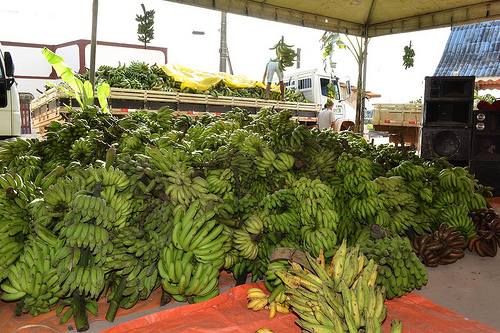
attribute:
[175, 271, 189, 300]
banana — green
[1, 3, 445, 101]
sky — white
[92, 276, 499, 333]
sheet — orange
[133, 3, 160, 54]
banana — hanging, bunched, green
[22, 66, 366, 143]
truck — standing, loaded, in daytime, white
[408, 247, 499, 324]
ground — brown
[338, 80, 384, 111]
shed — yellow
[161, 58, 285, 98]
cover — yellow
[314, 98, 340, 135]
person — standing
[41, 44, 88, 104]
leaf — green